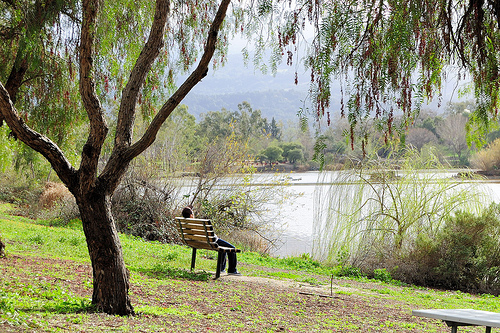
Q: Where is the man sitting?
A: Bench.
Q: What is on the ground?
A: Grass.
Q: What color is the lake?
A: Gray.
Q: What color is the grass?
A: Green.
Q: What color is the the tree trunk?
A: Brown.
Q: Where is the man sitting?
A: Bench.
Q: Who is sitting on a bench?
A: A person.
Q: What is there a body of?
A: Water.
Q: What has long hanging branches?
A: A tree.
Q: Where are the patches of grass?
A: On the ground.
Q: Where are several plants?
A: Along side of the water.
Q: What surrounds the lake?
A: Trees.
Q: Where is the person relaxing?
A: On a bench.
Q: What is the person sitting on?
A: A bench.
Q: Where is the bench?
A: By the water.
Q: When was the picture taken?
A: Daytime.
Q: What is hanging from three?
A: Leaves.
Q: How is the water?
A: Calm.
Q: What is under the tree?
A: A shadow.